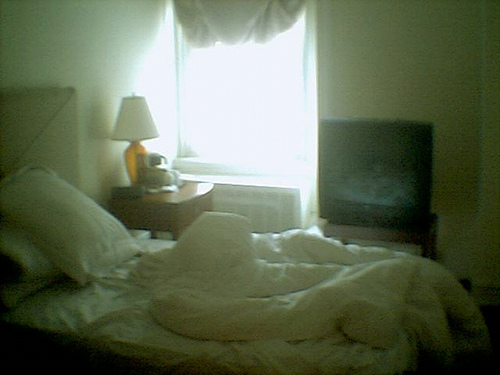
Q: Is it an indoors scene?
A: Yes, it is indoors.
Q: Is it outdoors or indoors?
A: It is indoors.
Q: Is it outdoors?
A: No, it is indoors.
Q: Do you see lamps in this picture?
A: Yes, there is a lamp.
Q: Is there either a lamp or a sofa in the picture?
A: Yes, there is a lamp.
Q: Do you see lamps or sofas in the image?
A: Yes, there is a lamp.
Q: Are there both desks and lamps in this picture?
A: No, there is a lamp but no desks.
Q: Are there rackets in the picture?
A: No, there are no rackets.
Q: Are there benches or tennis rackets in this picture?
A: No, there are no tennis rackets or benches.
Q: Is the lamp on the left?
A: Yes, the lamp is on the left of the image.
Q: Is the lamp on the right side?
A: No, the lamp is on the left of the image.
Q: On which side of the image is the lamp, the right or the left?
A: The lamp is on the left of the image.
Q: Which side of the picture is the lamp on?
A: The lamp is on the left of the image.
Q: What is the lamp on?
A: The lamp is on the nightstand.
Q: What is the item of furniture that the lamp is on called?
A: The piece of furniture is a nightstand.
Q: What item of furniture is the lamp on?
A: The lamp is on the nightstand.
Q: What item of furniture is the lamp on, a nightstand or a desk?
A: The lamp is on a nightstand.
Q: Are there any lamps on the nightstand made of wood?
A: Yes, there is a lamp on the nightstand.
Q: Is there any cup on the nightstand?
A: No, there is a lamp on the nightstand.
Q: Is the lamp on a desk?
A: No, the lamp is on the nightstand.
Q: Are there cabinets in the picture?
A: No, there are no cabinets.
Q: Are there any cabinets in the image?
A: No, there are no cabinets.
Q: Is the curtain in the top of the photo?
A: Yes, the curtain is in the top of the image.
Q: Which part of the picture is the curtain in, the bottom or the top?
A: The curtain is in the top of the image.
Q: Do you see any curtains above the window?
A: Yes, there is a curtain above the window.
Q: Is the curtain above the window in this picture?
A: Yes, the curtain is above the window.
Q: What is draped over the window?
A: The curtain is draped over the window.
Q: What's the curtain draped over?
A: The curtain is draped over the window.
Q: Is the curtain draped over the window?
A: Yes, the curtain is draped over the window.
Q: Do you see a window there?
A: Yes, there is a window.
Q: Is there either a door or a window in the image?
A: Yes, there is a window.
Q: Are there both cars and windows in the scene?
A: No, there is a window but no cars.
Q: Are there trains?
A: No, there are no trains.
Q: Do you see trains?
A: No, there are no trains.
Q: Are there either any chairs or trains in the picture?
A: No, there are no trains or chairs.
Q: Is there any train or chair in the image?
A: No, there are no trains or chairs.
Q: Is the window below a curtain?
A: Yes, the window is below a curtain.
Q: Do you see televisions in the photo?
A: Yes, there is a television.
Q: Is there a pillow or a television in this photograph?
A: Yes, there is a television.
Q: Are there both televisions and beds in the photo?
A: Yes, there are both a television and a bed.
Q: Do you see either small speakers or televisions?
A: Yes, there is a small television.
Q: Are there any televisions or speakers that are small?
A: Yes, the television is small.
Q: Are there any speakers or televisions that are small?
A: Yes, the television is small.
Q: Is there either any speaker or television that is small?
A: Yes, the television is small.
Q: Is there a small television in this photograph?
A: Yes, there is a small television.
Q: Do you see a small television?
A: Yes, there is a small television.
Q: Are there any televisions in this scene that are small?
A: Yes, there is a television that is small.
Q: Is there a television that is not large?
A: Yes, there is a small television.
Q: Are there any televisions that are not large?
A: Yes, there is a small television.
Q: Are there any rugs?
A: No, there are no rugs.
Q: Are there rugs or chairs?
A: No, there are no rugs or chairs.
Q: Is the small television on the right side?
A: Yes, the TV is on the right of the image.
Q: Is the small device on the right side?
A: Yes, the TV is on the right of the image.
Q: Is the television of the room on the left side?
A: No, the television is on the right of the image.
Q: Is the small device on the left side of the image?
A: No, the television is on the right of the image.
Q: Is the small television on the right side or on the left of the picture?
A: The TV is on the right of the image.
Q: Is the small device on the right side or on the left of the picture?
A: The TV is on the right of the image.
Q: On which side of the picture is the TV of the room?
A: The TV is on the right of the image.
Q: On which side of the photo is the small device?
A: The TV is on the right of the image.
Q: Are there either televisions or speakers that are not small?
A: No, there is a television but it is small.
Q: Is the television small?
A: Yes, the television is small.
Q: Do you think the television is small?
A: Yes, the television is small.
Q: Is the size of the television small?
A: Yes, the television is small.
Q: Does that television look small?
A: Yes, the television is small.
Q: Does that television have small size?
A: Yes, the television is small.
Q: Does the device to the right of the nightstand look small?
A: Yes, the television is small.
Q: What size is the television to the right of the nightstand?
A: The television is small.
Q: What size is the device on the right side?
A: The television is small.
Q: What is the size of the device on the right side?
A: The television is small.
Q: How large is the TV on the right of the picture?
A: The TV is small.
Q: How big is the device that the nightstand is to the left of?
A: The TV is small.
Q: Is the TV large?
A: No, the TV is small.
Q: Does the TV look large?
A: No, the TV is small.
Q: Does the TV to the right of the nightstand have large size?
A: No, the television is small.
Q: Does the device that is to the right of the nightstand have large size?
A: No, the television is small.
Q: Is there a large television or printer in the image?
A: No, there is a television but it is small.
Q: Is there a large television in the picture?
A: No, there is a television but it is small.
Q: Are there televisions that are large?
A: No, there is a television but it is small.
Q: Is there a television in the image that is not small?
A: No, there is a television but it is small.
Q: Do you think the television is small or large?
A: The television is small.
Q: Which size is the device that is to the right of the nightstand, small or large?
A: The television is small.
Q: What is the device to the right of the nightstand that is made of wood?
A: The device is a television.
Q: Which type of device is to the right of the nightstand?
A: The device is a television.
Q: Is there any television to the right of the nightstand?
A: Yes, there is a television to the right of the nightstand.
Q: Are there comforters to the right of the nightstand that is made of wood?
A: No, there is a television to the right of the nightstand.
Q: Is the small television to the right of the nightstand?
A: Yes, the TV is to the right of the nightstand.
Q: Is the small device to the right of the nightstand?
A: Yes, the TV is to the right of the nightstand.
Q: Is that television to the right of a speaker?
A: No, the television is to the right of the nightstand.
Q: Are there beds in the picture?
A: Yes, there is a bed.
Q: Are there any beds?
A: Yes, there is a bed.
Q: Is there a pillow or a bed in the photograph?
A: Yes, there is a bed.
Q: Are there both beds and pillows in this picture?
A: Yes, there are both a bed and a pillow.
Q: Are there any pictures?
A: No, there are no pictures.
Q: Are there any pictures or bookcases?
A: No, there are no pictures or bookcases.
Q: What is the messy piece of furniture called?
A: The piece of furniture is a bed.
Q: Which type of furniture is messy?
A: The furniture is a bed.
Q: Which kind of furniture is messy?
A: The furniture is a bed.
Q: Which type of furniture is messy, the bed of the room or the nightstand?
A: The bed is messy.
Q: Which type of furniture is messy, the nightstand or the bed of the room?
A: The bed is messy.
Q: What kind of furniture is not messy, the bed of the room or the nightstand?
A: The nightstand is not messy.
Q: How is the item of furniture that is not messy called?
A: The piece of furniture is a nightstand.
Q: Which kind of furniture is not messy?
A: The furniture is a nightstand.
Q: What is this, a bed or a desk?
A: This is a bed.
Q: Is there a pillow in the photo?
A: Yes, there is a pillow.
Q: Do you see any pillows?
A: Yes, there is a pillow.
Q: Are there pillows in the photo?
A: Yes, there is a pillow.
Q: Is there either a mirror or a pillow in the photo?
A: Yes, there is a pillow.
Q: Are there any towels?
A: No, there are no towels.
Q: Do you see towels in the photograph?
A: No, there are no towels.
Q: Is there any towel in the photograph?
A: No, there are no towels.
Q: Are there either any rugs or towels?
A: No, there are no towels or rugs.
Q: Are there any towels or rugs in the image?
A: No, there are no towels or rugs.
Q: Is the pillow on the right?
A: No, the pillow is on the left of the image.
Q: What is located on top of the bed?
A: The pillow is on top of the bed.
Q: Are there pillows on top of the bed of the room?
A: Yes, there is a pillow on top of the bed.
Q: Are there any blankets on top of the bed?
A: No, there is a pillow on top of the bed.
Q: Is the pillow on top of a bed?
A: Yes, the pillow is on top of a bed.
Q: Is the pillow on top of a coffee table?
A: No, the pillow is on top of a bed.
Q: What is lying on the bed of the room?
A: The pillow is lying on the bed.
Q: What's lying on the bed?
A: The pillow is lying on the bed.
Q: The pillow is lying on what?
A: The pillow is lying on the bed.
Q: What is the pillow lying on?
A: The pillow is lying on the bed.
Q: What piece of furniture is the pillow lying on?
A: The pillow is lying on the bed.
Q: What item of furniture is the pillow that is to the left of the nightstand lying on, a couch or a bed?
A: The pillow is lying on a bed.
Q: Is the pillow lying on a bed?
A: Yes, the pillow is lying on a bed.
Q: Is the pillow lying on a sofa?
A: No, the pillow is lying on a bed.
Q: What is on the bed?
A: The pillow is on the bed.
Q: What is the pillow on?
A: The pillow is on the bed.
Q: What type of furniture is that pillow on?
A: The pillow is on the bed.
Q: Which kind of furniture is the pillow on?
A: The pillow is on the bed.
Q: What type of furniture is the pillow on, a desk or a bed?
A: The pillow is on a bed.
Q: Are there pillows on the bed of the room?
A: Yes, there is a pillow on the bed.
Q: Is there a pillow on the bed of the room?
A: Yes, there is a pillow on the bed.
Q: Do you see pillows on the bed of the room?
A: Yes, there is a pillow on the bed.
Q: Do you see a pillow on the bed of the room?
A: Yes, there is a pillow on the bed.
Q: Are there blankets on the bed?
A: No, there is a pillow on the bed.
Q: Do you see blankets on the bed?
A: No, there is a pillow on the bed.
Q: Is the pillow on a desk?
A: No, the pillow is on the bed.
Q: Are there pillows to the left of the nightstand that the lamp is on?
A: Yes, there is a pillow to the left of the nightstand.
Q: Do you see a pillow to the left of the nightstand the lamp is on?
A: Yes, there is a pillow to the left of the nightstand.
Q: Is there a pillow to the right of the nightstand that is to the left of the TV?
A: No, the pillow is to the left of the nightstand.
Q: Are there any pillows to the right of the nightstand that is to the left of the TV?
A: No, the pillow is to the left of the nightstand.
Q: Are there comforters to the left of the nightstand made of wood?
A: No, there is a pillow to the left of the nightstand.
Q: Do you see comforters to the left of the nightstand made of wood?
A: No, there is a pillow to the left of the nightstand.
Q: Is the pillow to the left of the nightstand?
A: Yes, the pillow is to the left of the nightstand.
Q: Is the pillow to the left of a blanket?
A: No, the pillow is to the left of the nightstand.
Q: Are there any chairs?
A: No, there are no chairs.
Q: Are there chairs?
A: No, there are no chairs.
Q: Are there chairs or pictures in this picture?
A: No, there are no chairs or pictures.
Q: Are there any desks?
A: No, there are no desks.